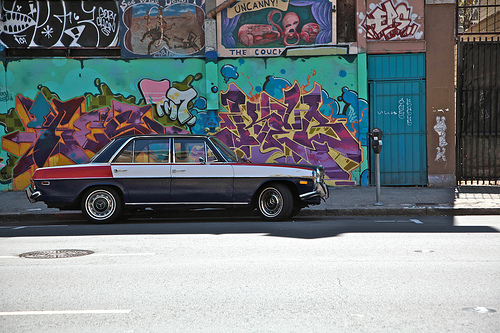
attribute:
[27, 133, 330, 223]
car — black, parked, red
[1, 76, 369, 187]
graffiti — black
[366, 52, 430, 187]
door — barred, blue, black, teal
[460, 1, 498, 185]
gate — black, metal, security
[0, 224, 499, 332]
street — paved, shady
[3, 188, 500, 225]
sidewalk — shadowy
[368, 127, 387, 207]
meter — black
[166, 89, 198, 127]
number — seven